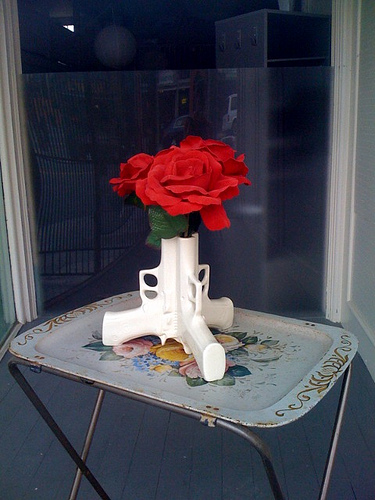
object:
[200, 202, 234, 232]
petal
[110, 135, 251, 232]
flower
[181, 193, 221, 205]
petal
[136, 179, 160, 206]
petal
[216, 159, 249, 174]
petal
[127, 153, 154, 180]
petal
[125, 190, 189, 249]
leaf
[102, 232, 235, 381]
vase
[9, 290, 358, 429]
tray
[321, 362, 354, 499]
leg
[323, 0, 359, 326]
frame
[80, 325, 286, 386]
image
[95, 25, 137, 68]
light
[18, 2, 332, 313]
window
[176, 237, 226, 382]
gun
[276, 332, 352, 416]
design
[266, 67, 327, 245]
shadow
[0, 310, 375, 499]
floor